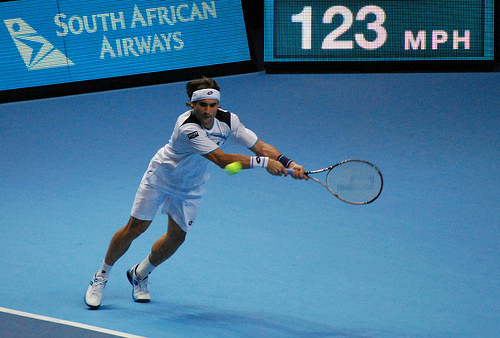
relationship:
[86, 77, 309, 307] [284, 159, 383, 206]
man holding racket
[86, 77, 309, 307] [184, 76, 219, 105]
man has hair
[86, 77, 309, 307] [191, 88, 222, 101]
man wearing headband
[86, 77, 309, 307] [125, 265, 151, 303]
man wearing tennis shoes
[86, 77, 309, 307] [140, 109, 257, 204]
man wearing shirt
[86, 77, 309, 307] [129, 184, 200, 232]
man wearing shorts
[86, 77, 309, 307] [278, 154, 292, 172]
man wearing wristband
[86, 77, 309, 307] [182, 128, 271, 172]
man stretching arm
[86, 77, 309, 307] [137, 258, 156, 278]
man wearing sock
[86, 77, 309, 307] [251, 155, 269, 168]
man wearing wristband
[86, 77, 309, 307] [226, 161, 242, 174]
man hitting tennis ball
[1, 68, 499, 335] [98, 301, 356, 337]
floor has shadow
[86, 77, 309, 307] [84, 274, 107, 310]
man wearing tennis shoe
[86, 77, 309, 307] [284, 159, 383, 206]
man swinging racket